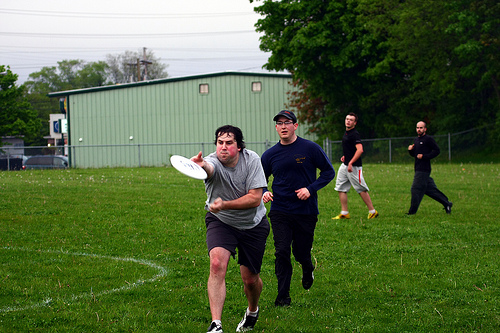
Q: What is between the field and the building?
A: A fence.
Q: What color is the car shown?
A: Green.